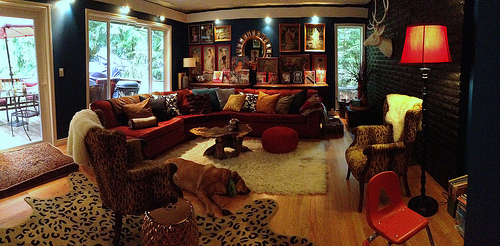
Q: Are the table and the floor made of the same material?
A: Yes, both the table and the floor are made of wood.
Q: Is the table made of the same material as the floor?
A: Yes, both the table and the floor are made of wood.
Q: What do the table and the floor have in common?
A: The material, both the table and the floor are wooden.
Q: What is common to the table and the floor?
A: The material, both the table and the floor are wooden.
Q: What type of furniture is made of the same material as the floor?
A: The table is made of the same material as the floor.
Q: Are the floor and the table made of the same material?
A: Yes, both the floor and the table are made of wood.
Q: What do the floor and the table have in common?
A: The material, both the floor and the table are wooden.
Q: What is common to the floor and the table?
A: The material, both the floor and the table are wooden.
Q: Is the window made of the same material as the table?
A: No, the window is made of glass and the table is made of wood.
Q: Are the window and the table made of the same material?
A: No, the window is made of glass and the table is made of wood.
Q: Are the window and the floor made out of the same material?
A: No, the window is made of glass and the floor is made of wood.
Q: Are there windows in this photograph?
A: Yes, there is a window.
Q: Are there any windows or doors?
A: Yes, there is a window.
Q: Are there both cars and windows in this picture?
A: No, there is a window but no cars.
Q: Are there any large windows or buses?
A: Yes, there is a large window.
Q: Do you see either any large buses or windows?
A: Yes, there is a large window.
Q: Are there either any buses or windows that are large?
A: Yes, the window is large.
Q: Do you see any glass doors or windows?
A: Yes, there is a glass window.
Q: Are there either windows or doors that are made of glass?
A: Yes, the window is made of glass.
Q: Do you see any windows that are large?
A: Yes, there is a window that is large.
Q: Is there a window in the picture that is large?
A: Yes, there is a window that is large.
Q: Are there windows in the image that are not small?
A: Yes, there is a large window.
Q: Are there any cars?
A: No, there are no cars.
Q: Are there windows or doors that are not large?
A: No, there is a window but it is large.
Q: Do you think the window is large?
A: Yes, the window is large.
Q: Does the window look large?
A: Yes, the window is large.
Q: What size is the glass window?
A: The window is large.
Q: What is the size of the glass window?
A: The window is large.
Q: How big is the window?
A: The window is large.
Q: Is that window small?
A: No, the window is large.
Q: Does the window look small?
A: No, the window is large.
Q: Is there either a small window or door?
A: No, there is a window but it is large.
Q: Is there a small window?
A: No, there is a window but it is large.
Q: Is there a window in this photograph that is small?
A: No, there is a window but it is large.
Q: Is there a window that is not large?
A: No, there is a window but it is large.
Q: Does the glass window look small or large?
A: The window is large.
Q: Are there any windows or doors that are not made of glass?
A: No, there is a window but it is made of glass.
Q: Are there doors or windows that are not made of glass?
A: No, there is a window but it is made of glass.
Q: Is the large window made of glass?
A: Yes, the window is made of glass.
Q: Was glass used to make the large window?
A: Yes, the window is made of glass.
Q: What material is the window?
A: The window is made of glass.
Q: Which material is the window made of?
A: The window is made of glass.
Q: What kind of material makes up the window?
A: The window is made of glass.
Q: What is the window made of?
A: The window is made of glass.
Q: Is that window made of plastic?
A: No, the window is made of glass.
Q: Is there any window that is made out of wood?
A: No, there is a window but it is made of glass.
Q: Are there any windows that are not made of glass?
A: No, there is a window but it is made of glass.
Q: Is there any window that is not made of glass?
A: No, there is a window but it is made of glass.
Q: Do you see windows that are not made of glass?
A: No, there is a window but it is made of glass.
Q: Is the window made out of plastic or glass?
A: The window is made of glass.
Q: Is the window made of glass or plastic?
A: The window is made of glass.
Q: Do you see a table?
A: Yes, there is a table.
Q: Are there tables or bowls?
A: Yes, there is a table.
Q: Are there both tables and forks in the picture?
A: No, there is a table but no forks.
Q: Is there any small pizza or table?
A: Yes, there is a small table.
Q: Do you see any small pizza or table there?
A: Yes, there is a small table.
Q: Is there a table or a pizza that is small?
A: Yes, the table is small.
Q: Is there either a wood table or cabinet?
A: Yes, there is a wood table.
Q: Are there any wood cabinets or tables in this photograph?
A: Yes, there is a wood table.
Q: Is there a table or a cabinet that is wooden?
A: Yes, the table is wooden.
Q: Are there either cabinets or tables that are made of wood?
A: Yes, the table is made of wood.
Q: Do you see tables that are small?
A: Yes, there is a small table.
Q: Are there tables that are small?
A: Yes, there is a table that is small.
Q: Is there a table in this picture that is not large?
A: Yes, there is a small table.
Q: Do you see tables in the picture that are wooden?
A: Yes, there is a wood table.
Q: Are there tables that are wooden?
A: Yes, there is a table that is wooden.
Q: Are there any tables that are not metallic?
A: Yes, there is a wooden table.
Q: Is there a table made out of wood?
A: Yes, there is a table that is made of wood.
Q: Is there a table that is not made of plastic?
A: Yes, there is a table that is made of wood.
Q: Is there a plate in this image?
A: No, there are no plates.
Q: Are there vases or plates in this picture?
A: No, there are no plates or vases.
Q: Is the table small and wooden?
A: Yes, the table is small and wooden.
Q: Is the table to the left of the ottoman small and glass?
A: No, the table is small but wooden.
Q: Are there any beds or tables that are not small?
A: No, there is a table but it is small.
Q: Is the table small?
A: Yes, the table is small.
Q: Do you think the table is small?
A: Yes, the table is small.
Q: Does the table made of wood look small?
A: Yes, the table is small.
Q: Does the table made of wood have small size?
A: Yes, the table is small.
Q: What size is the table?
A: The table is small.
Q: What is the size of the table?
A: The table is small.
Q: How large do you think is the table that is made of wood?
A: The table is small.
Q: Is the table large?
A: No, the table is small.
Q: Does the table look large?
A: No, the table is small.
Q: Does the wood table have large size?
A: No, the table is small.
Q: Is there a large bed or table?
A: No, there is a table but it is small.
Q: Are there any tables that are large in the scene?
A: No, there is a table but it is small.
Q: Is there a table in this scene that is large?
A: No, there is a table but it is small.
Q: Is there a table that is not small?
A: No, there is a table but it is small.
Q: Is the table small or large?
A: The table is small.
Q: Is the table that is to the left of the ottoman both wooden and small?
A: Yes, the table is wooden and small.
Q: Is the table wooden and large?
A: No, the table is wooden but small.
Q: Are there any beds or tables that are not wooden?
A: No, there is a table but it is wooden.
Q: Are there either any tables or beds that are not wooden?
A: No, there is a table but it is wooden.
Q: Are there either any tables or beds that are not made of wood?
A: No, there is a table but it is made of wood.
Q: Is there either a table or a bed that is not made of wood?
A: No, there is a table but it is made of wood.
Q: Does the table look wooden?
A: Yes, the table is wooden.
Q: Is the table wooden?
A: Yes, the table is wooden.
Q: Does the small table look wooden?
A: Yes, the table is wooden.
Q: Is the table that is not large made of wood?
A: Yes, the table is made of wood.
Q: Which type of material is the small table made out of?
A: The table is made of wood.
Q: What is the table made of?
A: The table is made of wood.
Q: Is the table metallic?
A: No, the table is wooden.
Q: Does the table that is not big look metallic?
A: No, the table is wooden.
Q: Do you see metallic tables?
A: No, there is a table but it is wooden.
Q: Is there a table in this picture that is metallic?
A: No, there is a table but it is wooden.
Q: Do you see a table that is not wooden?
A: No, there is a table but it is wooden.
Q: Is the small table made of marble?
A: No, the table is made of wood.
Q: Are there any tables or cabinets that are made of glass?
A: No, there is a table but it is made of wood.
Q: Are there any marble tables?
A: No, there is a table but it is made of wood.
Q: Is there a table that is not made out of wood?
A: No, there is a table but it is made of wood.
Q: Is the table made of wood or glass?
A: The table is made of wood.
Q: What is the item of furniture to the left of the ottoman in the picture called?
A: The piece of furniture is a table.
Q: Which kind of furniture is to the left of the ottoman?
A: The piece of furniture is a table.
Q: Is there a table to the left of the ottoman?
A: Yes, there is a table to the left of the ottoman.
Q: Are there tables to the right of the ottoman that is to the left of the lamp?
A: No, the table is to the left of the ottoman.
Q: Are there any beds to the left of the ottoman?
A: No, there is a table to the left of the ottoman.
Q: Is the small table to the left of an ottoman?
A: Yes, the table is to the left of an ottoman.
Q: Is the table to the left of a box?
A: No, the table is to the left of an ottoman.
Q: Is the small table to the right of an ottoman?
A: No, the table is to the left of an ottoman.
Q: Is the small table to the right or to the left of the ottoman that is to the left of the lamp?
A: The table is to the left of the ottoman.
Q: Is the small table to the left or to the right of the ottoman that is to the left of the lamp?
A: The table is to the left of the ottoman.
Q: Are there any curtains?
A: No, there are no curtains.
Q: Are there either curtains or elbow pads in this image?
A: No, there are no curtains or elbow pads.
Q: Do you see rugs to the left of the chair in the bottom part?
A: Yes, there is a rug to the left of the chair.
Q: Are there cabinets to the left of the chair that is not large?
A: No, there is a rug to the left of the chair.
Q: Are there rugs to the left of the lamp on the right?
A: Yes, there is a rug to the left of the lamp.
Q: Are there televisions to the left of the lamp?
A: No, there is a rug to the left of the lamp.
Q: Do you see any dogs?
A: Yes, there is a dog.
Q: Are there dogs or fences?
A: Yes, there is a dog.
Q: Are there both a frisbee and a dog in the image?
A: No, there is a dog but no frisbees.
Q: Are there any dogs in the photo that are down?
A: Yes, there is a dog that is down.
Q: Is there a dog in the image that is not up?
A: Yes, there is a dog that is down.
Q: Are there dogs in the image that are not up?
A: Yes, there is a dog that is down.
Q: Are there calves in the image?
A: No, there are no calves.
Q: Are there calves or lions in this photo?
A: No, there are no calves or lions.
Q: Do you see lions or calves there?
A: No, there are no calves or lions.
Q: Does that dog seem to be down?
A: Yes, the dog is down.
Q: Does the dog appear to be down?
A: Yes, the dog is down.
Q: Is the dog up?
A: No, the dog is down.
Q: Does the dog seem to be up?
A: No, the dog is down.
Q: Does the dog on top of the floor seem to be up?
A: No, the dog is down.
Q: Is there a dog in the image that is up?
A: No, there is a dog but it is down.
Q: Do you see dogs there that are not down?
A: No, there is a dog but it is down.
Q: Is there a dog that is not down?
A: No, there is a dog but it is down.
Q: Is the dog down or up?
A: The dog is down.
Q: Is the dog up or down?
A: The dog is down.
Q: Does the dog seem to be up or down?
A: The dog is down.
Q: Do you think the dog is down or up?
A: The dog is down.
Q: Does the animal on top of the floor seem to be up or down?
A: The dog is down.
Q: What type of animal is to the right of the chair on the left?
A: The animal is a dog.